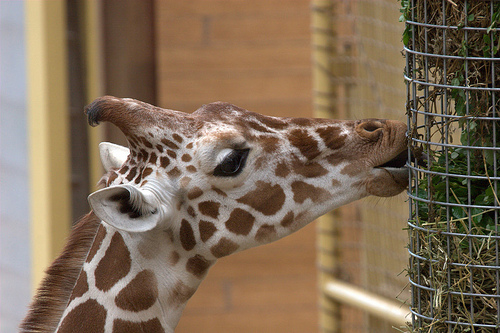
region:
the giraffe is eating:
[62, 74, 429, 291]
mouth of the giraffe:
[330, 80, 405, 202]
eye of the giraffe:
[206, 142, 270, 201]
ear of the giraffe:
[79, 182, 186, 232]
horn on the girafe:
[5, 43, 202, 146]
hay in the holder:
[431, 216, 488, 292]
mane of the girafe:
[11, 222, 83, 330]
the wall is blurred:
[222, 287, 307, 330]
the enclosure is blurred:
[290, 225, 399, 324]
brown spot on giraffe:
[316, 125, 348, 151]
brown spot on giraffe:
[283, 124, 319, 157]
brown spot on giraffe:
[291, 150, 327, 177]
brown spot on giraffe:
[275, 156, 289, 177]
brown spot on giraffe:
[291, 178, 331, 203]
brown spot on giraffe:
[279, 208, 297, 230]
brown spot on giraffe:
[238, 177, 284, 214]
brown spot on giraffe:
[223, 204, 254, 236]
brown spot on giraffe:
[196, 195, 220, 222]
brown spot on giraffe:
[178, 213, 197, 255]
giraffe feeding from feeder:
[16, 54, 441, 326]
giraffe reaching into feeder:
[3, 79, 400, 331]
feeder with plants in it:
[391, 5, 499, 326]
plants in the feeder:
[413, 8, 493, 307]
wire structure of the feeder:
[434, 195, 483, 213]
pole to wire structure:
[297, 13, 347, 329]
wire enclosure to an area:
[327, 20, 410, 295]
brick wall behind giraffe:
[162, 15, 322, 318]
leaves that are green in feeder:
[451, 173, 489, 207]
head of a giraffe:
[68, 64, 436, 293]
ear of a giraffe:
[86, 170, 168, 240]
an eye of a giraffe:
[205, 134, 266, 192]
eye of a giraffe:
[198, 122, 272, 189]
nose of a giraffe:
[354, 112, 402, 138]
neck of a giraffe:
[33, 237, 253, 328]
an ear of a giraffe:
[69, 170, 177, 253]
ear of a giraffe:
[88, 137, 142, 181]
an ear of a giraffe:
[83, 139, 142, 181]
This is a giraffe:
[14, 84, 419, 328]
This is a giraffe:
[7, 72, 421, 329]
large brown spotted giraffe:
[10, 89, 408, 332]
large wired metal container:
[400, 9, 499, 331]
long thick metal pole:
[322, 279, 410, 332]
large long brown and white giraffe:
[21, 96, 411, 332]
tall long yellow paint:
[24, 0, 72, 299]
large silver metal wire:
[396, 4, 499, 332]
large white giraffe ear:
[84, 187, 164, 233]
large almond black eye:
[211, 142, 250, 179]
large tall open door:
[98, 4, 367, 332]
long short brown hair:
[16, 207, 98, 332]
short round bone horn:
[87, 95, 189, 145]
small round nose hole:
[357, 116, 384, 137]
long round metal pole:
[320, 279, 412, 332]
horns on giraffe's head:
[69, 83, 189, 152]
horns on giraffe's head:
[73, 66, 188, 157]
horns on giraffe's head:
[67, 78, 189, 151]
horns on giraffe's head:
[75, 77, 189, 154]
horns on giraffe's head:
[74, 80, 189, 160]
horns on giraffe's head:
[79, 78, 190, 160]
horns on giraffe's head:
[78, 82, 183, 157]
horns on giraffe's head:
[75, 82, 197, 163]